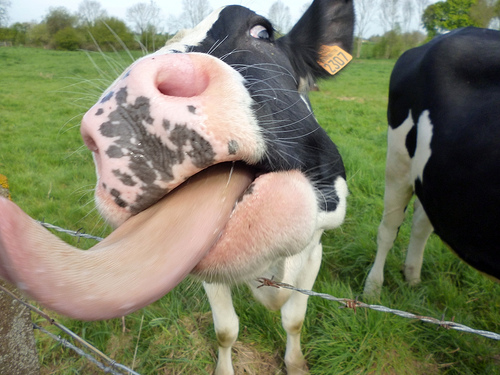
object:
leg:
[278, 243, 322, 373]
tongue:
[0, 170, 252, 321]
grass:
[14, 79, 53, 151]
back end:
[361, 42, 432, 299]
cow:
[0, 0, 360, 374]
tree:
[0, 21, 29, 49]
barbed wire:
[255, 275, 500, 341]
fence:
[257, 275, 499, 341]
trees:
[86, 15, 138, 51]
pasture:
[29, 52, 84, 93]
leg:
[404, 199, 435, 286]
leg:
[198, 281, 243, 374]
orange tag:
[315, 41, 355, 77]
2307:
[321, 50, 350, 73]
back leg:
[369, 120, 412, 274]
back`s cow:
[361, 25, 499, 301]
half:
[360, 26, 498, 304]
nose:
[79, 51, 229, 181]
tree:
[43, 27, 87, 52]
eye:
[246, 23, 273, 44]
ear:
[277, 0, 356, 83]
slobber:
[219, 160, 235, 204]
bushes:
[0, 0, 435, 61]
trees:
[417, 0, 499, 44]